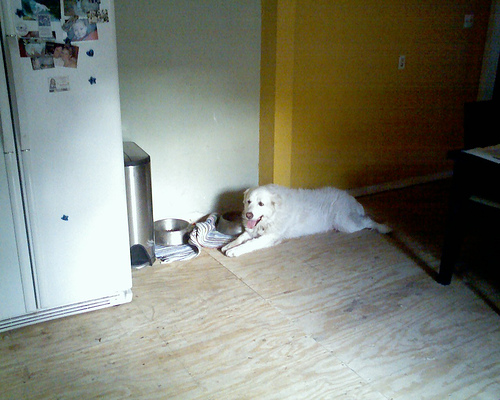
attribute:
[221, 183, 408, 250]
dog — laying, white, panting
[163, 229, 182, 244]
bowl — aluminum, silver, food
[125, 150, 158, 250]
garbage can — silver, aluminum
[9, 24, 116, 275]
fridge — white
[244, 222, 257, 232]
tongue — pink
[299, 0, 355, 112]
wall — yellow, painted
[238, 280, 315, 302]
floor — wooden